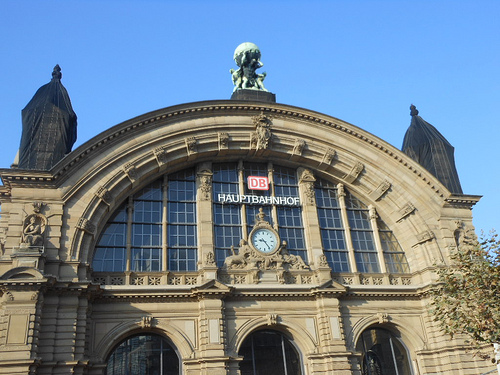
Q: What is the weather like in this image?
A: It is clear.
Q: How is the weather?
A: It is clear.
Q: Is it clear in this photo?
A: Yes, it is clear.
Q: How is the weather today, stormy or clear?
A: It is clear.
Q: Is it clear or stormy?
A: It is clear.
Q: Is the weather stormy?
A: No, it is clear.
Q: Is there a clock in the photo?
A: Yes, there is a clock.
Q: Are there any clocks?
A: Yes, there is a clock.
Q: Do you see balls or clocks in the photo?
A: Yes, there is a clock.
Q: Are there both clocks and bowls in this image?
A: No, there is a clock but no bowls.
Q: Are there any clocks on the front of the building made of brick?
A: Yes, there is a clock on the front of the building.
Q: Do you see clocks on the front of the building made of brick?
A: Yes, there is a clock on the front of the building.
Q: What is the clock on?
A: The clock is on the building.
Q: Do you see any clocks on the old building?
A: Yes, there is a clock on the building.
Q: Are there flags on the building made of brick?
A: No, there is a clock on the building.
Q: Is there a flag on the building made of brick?
A: No, there is a clock on the building.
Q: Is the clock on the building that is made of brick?
A: Yes, the clock is on the building.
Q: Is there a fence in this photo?
A: No, there are no fences.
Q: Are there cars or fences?
A: No, there are no fences or cars.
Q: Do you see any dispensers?
A: No, there are no dispensers.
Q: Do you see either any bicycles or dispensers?
A: No, there are no dispensers or bicycles.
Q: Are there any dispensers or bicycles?
A: No, there are no dispensers or bicycles.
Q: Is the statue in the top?
A: Yes, the statue is in the top of the image.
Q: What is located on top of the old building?
A: The statue is on top of the building.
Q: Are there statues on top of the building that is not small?
A: Yes, there is a statue on top of the building.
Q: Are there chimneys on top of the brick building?
A: No, there is a statue on top of the building.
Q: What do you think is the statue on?
A: The statue is on the building.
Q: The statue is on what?
A: The statue is on the building.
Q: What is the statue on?
A: The statue is on the building.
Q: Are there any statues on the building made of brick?
A: Yes, there is a statue on the building.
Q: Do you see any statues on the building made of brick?
A: Yes, there is a statue on the building.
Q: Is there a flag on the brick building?
A: No, there is a statue on the building.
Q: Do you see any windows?
A: Yes, there is a window.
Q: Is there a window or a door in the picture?
A: Yes, there is a window.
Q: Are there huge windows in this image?
A: Yes, there is a huge window.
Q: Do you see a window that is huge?
A: Yes, there is a window that is huge.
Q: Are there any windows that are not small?
A: Yes, there is a huge window.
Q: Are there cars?
A: No, there are no cars.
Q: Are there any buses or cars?
A: No, there are no cars or buses.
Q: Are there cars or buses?
A: No, there are no cars or buses.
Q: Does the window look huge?
A: Yes, the window is huge.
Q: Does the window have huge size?
A: Yes, the window is huge.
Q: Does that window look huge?
A: Yes, the window is huge.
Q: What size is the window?
A: The window is huge.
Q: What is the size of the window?
A: The window is huge.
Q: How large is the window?
A: The window is huge.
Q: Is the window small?
A: No, the window is huge.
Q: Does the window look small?
A: No, the window is huge.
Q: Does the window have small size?
A: No, the window is huge.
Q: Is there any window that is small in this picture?
A: No, there is a window but it is huge.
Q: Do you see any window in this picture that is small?
A: No, there is a window but it is huge.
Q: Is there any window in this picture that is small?
A: No, there is a window but it is huge.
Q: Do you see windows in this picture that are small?
A: No, there is a window but it is huge.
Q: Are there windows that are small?
A: No, there is a window but it is huge.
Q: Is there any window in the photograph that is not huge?
A: No, there is a window but it is huge.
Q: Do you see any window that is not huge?
A: No, there is a window but it is huge.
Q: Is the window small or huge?
A: The window is huge.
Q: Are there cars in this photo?
A: No, there are no cars.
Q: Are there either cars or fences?
A: No, there are no cars or fences.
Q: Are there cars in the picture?
A: No, there are no cars.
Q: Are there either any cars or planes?
A: No, there are no cars or planes.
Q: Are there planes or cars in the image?
A: No, there are no cars or planes.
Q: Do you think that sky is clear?
A: Yes, the sky is clear.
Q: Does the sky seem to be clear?
A: Yes, the sky is clear.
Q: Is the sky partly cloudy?
A: No, the sky is clear.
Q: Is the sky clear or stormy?
A: The sky is clear.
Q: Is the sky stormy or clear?
A: The sky is clear.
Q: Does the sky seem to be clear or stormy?
A: The sky is clear.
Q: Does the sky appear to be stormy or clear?
A: The sky is clear.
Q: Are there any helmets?
A: No, there are no helmets.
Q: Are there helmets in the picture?
A: No, there are no helmets.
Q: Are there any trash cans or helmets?
A: No, there are no helmets or trash cans.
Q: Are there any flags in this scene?
A: No, there are no flags.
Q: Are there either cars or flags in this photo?
A: No, there are no flags or cars.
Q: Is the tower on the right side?
A: Yes, the tower is on the right of the image.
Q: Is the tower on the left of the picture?
A: No, the tower is on the right of the image.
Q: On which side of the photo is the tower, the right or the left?
A: The tower is on the right of the image.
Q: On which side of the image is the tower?
A: The tower is on the right of the image.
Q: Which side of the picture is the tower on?
A: The tower is on the right of the image.